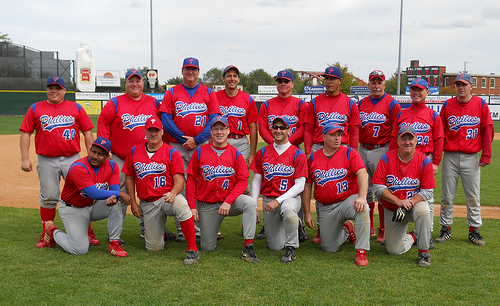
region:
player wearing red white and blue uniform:
[21, 71, 86, 159]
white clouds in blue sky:
[160, 15, 195, 50]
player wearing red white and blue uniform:
[196, 115, 241, 205]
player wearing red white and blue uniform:
[263, 108, 298, 208]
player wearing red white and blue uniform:
[310, 103, 360, 203]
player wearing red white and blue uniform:
[383, 127, 440, 220]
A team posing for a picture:
[8, 25, 489, 265]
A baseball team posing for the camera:
[9, 45, 493, 270]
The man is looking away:
[81, 134, 123, 206]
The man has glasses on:
[264, 118, 294, 152]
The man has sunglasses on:
[269, 118, 292, 146]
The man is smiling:
[270, 117, 290, 144]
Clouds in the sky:
[211, 9, 351, 54]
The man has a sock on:
[178, 213, 200, 261]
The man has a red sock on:
[177, 212, 200, 252]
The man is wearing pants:
[53, 196, 125, 246]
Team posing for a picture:
[8, 33, 491, 280]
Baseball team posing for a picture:
[23, 45, 491, 261]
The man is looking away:
[80, 130, 116, 181]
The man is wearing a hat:
[86, 137, 114, 173]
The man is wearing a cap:
[83, 130, 113, 174]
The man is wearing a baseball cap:
[83, 133, 111, 176]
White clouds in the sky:
[248, 10, 331, 52]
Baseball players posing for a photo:
[23, 63, 490, 261]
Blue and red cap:
[274, 71, 298, 83]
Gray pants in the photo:
[134, 201, 181, 241]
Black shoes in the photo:
[226, 242, 293, 270]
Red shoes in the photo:
[341, 219, 371, 267]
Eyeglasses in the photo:
[266, 77, 296, 89]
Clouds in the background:
[249, 13, 355, 51]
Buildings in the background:
[383, 63, 480, 85]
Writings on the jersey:
[32, 109, 84, 141]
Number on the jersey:
[329, 169, 349, 199]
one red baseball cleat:
[350, 240, 371, 266]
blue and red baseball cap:
[176, 54, 203, 74]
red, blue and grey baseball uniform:
[435, 91, 497, 233]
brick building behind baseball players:
[391, 58, 498, 96]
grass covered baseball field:
[3, 113, 497, 303]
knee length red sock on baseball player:
[36, 205, 59, 233]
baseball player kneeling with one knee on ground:
[39, 129, 136, 265]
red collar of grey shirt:
[211, 140, 229, 152]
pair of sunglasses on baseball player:
[268, 122, 288, 132]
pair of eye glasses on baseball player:
[206, 123, 230, 135]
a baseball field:
[2, 108, 493, 303]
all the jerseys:
[18, 90, 499, 207]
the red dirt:
[1, 125, 498, 209]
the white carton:
[71, 38, 97, 91]